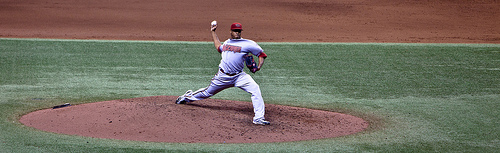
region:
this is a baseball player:
[193, 22, 270, 120]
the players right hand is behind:
[203, 20, 220, 48]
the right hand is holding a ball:
[206, 17, 216, 24]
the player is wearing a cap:
[233, 24, 240, 29]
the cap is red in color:
[231, 22, 241, 29]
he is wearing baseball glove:
[245, 56, 257, 71]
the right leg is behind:
[178, 70, 218, 102]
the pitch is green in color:
[371, 59, 477, 121]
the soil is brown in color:
[98, 104, 169, 127]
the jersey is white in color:
[222, 46, 242, 63]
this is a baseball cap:
[231, 21, 244, 32]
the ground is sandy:
[143, 104, 215, 138]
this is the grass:
[330, 49, 452, 101]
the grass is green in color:
[363, 60, 470, 87]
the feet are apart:
[173, 77, 269, 124]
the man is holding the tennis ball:
[208, 15, 224, 52]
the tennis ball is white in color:
[206, 20, 223, 33]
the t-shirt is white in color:
[224, 55, 237, 70]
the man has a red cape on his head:
[222, 21, 248, 33]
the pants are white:
[180, 75, 275, 115]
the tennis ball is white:
[200, 15, 225, 35]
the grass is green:
[363, 73, 448, 125]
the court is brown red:
[331, 13, 476, 46]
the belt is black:
[213, 68, 251, 74]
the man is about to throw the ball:
[193, 11, 289, 117]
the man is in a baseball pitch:
[0, 4, 499, 133]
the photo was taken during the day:
[2, 2, 499, 146]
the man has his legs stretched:
[190, 6, 297, 151]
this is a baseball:
[204, 18, 219, 28]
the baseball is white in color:
[206, 15, 219, 31]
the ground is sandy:
[141, 107, 186, 133]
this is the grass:
[362, 60, 456, 129]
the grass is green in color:
[366, 67, 446, 141]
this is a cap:
[230, 21, 243, 33]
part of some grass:
[401, 76, 456, 128]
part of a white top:
[227, 60, 242, 70]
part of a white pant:
[237, 80, 255, 97]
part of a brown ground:
[148, 113, 201, 134]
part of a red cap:
[228, 19, 245, 29]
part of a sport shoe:
[178, 91, 195, 105]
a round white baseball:
[206, 16, 216, 29]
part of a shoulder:
[244, 38, 264, 52]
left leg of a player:
[248, 90, 263, 112]